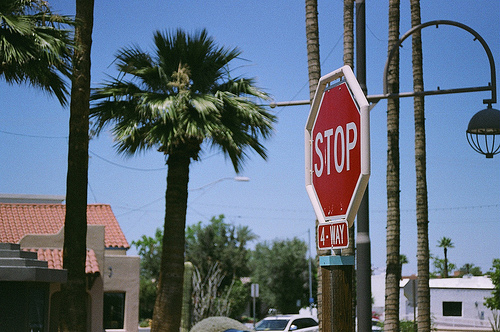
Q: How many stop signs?
A: 1.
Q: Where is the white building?
A: Back right.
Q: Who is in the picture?
A: No one.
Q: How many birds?
A: None.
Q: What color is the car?
A: White.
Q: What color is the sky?
A: Blue.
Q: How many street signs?
A: 2.